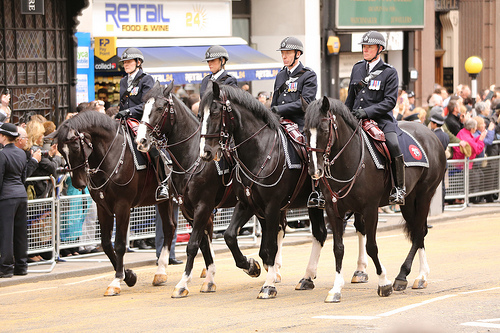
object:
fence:
[14, 137, 499, 272]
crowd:
[0, 82, 500, 204]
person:
[197, 42, 241, 117]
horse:
[133, 79, 243, 300]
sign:
[76, 1, 237, 40]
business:
[77, 1, 296, 128]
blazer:
[364, 79, 386, 91]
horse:
[197, 73, 328, 300]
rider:
[341, 27, 413, 207]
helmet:
[358, 29, 389, 48]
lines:
[310, 285, 500, 320]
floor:
[0, 212, 500, 332]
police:
[117, 48, 154, 126]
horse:
[132, 75, 287, 298]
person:
[267, 32, 328, 211]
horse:
[295, 94, 445, 302]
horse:
[53, 108, 174, 298]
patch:
[363, 79, 382, 91]